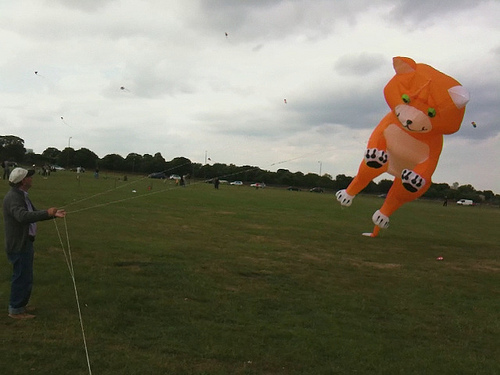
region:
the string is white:
[69, 321, 99, 347]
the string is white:
[71, 325, 93, 340]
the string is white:
[67, 293, 96, 324]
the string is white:
[67, 275, 79, 298]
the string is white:
[69, 286, 89, 318]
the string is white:
[76, 305, 87, 326]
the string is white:
[77, 328, 97, 356]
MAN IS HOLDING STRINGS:
[68, 290, 84, 308]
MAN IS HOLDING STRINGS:
[74, 308, 91, 330]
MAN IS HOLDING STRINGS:
[66, 319, 121, 356]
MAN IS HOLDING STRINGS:
[67, 316, 112, 334]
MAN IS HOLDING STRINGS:
[53, 297, 103, 325]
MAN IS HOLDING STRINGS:
[81, 338, 96, 345]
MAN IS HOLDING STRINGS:
[73, 312, 88, 322]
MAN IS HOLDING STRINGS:
[80, 327, 118, 343]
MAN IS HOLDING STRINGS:
[81, 350, 91, 354]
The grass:
[187, 264, 304, 373]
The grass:
[305, 311, 334, 353]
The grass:
[288, 277, 321, 360]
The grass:
[285, 335, 300, 373]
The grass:
[249, 251, 310, 367]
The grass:
[270, 296, 310, 373]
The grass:
[292, 305, 315, 351]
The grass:
[294, 311, 328, 364]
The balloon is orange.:
[312, 56, 490, 280]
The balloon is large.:
[322, 31, 482, 278]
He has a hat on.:
[12, 158, 79, 312]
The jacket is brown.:
[0, 149, 88, 337]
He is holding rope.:
[3, 151, 88, 315]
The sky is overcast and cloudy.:
[16, 6, 373, 156]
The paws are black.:
[355, 133, 450, 211]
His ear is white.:
[382, 43, 489, 170]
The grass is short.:
[76, 189, 420, 334]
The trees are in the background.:
[5, 118, 389, 205]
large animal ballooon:
[333, 33, 468, 259]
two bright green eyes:
[398, 91, 445, 120]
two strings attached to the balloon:
[61, 125, 412, 231]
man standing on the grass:
[3, 158, 83, 330]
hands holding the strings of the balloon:
[43, 197, 79, 236]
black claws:
[365, 140, 392, 163]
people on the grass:
[41, 161, 240, 191]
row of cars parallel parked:
[210, 171, 271, 189]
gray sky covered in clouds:
[1, 1, 499, 191]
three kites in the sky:
[24, 60, 149, 130]